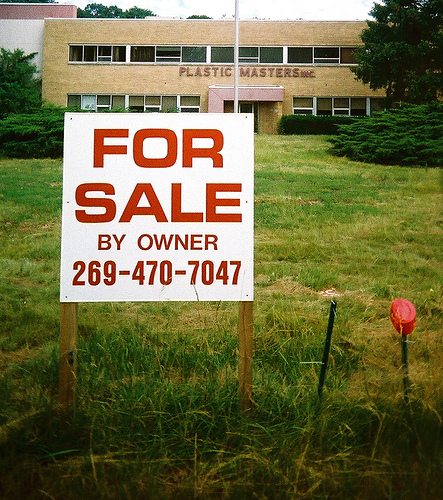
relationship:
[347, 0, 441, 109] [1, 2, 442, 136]
tree in front of brick building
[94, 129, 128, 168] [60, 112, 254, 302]
f on sign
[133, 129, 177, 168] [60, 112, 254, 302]
o on sign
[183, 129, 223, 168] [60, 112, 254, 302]
r on sign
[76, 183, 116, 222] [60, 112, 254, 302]
s on sign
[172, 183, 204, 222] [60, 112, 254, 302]
l on sign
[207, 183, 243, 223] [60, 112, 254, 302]
e on sign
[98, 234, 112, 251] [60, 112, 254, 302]
b on sign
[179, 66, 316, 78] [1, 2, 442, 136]
words on brick building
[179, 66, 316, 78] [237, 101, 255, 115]
words above entrance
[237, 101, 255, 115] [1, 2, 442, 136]
entrance of brick building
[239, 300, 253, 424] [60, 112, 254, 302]
wood holding up sign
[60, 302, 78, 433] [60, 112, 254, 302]
wood holding up sign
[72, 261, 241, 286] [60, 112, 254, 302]
contact information on sign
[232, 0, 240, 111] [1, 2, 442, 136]
pole in front of brick building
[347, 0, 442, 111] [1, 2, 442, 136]
tree around brick building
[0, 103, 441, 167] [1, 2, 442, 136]
shrubs near brick building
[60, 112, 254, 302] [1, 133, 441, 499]
sign on lawn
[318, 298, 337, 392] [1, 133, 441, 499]
pole in lawn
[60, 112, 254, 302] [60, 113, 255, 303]
sign has edges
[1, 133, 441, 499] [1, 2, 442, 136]
lawn in front of brick building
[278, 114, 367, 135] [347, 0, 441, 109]
shrub near tree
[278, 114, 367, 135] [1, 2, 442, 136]
shrub next to brick building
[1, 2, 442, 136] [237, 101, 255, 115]
brick building has an entrance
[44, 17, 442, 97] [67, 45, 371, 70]
upper floor has windows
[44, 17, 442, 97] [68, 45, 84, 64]
upper floor has a window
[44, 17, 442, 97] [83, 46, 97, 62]
upper floor has a window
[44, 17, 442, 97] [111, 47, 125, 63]
upper floor has a window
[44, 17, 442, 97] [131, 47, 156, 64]
upper floor has a window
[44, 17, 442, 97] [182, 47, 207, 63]
upper floor has a window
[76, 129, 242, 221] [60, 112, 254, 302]
for sale on sign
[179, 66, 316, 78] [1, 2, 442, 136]
words are on brick building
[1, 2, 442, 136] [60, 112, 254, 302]
brick building behind sign